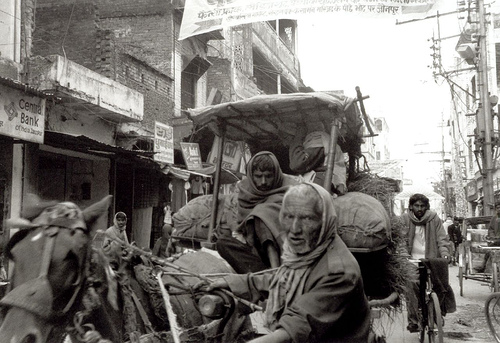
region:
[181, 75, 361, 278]
Man riding on wagon.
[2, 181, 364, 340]
Old man leading horse.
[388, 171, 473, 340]
Man riding bike near wagon.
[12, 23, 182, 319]
Large brick building along road.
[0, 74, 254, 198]
Signs on buildings along road.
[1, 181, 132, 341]
Horse wearing bridle and blinders.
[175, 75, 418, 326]
Bags of supplies on each side of wagon.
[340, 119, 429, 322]
Straw loaded onto wagon.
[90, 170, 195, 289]
Man standing along road watching.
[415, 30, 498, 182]
Power pole with wires on side of road.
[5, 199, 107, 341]
the horse has a harness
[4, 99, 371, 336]
the horse is pulling a cart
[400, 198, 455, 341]
a man is on a bicycle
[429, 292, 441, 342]
the tire is made of rubber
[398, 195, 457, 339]
the man is riding the bicycle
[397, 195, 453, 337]
the bicycle is moving thru the street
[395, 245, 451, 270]
the man is holding on to the handlebars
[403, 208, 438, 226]
the man is wearing a scarf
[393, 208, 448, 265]
the man is wearing a coat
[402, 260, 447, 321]
the man is wearing long pants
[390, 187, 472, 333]
A person on a bicycle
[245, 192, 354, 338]
A person pushing a cart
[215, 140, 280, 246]
A person sitted on a cart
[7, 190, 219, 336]
A brown horse pushing a cart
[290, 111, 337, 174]
A person sitted on a cart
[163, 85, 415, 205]
A paper horse cart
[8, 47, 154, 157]
An old buildings's wall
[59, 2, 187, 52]
An old buildings's wall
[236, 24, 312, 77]
An old buildings's wall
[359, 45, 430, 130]
A clear sky background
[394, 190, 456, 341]
Man riding on a bicycle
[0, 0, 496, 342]
Third world country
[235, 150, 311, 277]
Ill man wrapped in a blanket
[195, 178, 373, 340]
Elder man holding a horse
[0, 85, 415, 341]
Horse pulling a wood trailer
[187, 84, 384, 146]
Flimsy wood canopy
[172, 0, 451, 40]
Large white hanging banner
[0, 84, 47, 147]
Rectangular bank sign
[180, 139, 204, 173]
Lopsided store sign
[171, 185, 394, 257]
Large sacks on a cart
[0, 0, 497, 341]
People are on the street.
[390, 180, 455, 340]
The man is riding a bicycle.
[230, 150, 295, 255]
The man is wrapped in a robe.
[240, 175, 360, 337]
The man has a robe wrapped around his head.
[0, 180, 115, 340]
The horse has bridle on the face.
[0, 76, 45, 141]
A sign on the building.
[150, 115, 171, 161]
A second sign on the building.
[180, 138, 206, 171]
A third sign on the building.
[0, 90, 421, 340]
The horse is pulling a carriage.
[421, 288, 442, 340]
The front wheel on a bicycle.